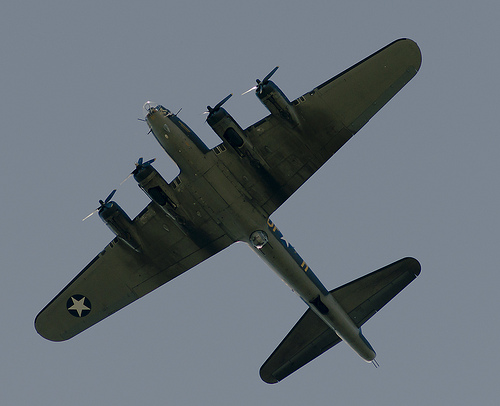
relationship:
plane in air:
[33, 28, 455, 375] [245, 15, 283, 38]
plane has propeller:
[33, 28, 455, 375] [239, 70, 281, 100]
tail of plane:
[272, 261, 423, 387] [33, 28, 455, 375]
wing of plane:
[221, 58, 458, 190] [33, 28, 455, 375]